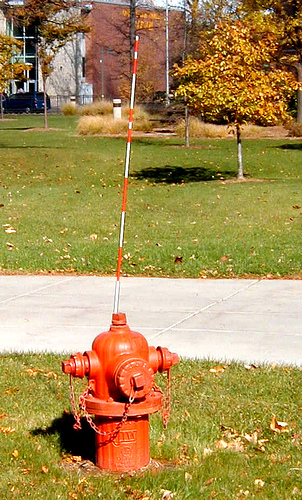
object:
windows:
[8, 12, 38, 92]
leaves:
[231, 63, 251, 122]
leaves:
[205, 18, 280, 74]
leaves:
[168, 53, 230, 80]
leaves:
[252, 67, 272, 122]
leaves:
[197, 80, 213, 123]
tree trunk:
[183, 115, 189, 146]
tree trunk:
[234, 139, 244, 179]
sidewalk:
[1, 274, 300, 365]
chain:
[69, 373, 90, 432]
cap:
[61, 352, 82, 379]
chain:
[81, 380, 138, 438]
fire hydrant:
[61, 313, 179, 471]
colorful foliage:
[168, 19, 302, 181]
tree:
[168, 22, 301, 179]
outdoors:
[0, 0, 300, 498]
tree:
[0, 30, 33, 119]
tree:
[0, 0, 91, 128]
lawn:
[1, 114, 301, 275]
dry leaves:
[174, 404, 300, 470]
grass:
[160, 168, 261, 234]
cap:
[156, 346, 178, 373]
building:
[1, 1, 200, 113]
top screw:
[112, 312, 125, 323]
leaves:
[199, 419, 232, 458]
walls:
[38, 1, 183, 99]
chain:
[154, 367, 172, 431]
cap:
[117, 358, 155, 401]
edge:
[2, 271, 300, 282]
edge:
[179, 349, 298, 367]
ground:
[1, 110, 300, 497]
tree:
[161, 1, 205, 147]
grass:
[0, 351, 300, 497]